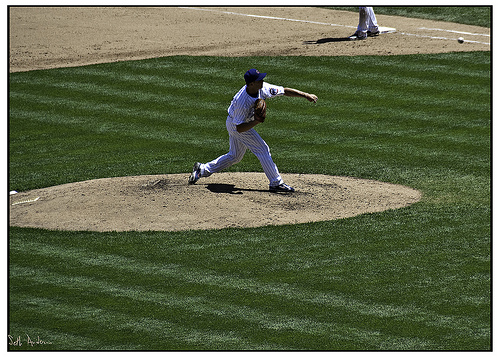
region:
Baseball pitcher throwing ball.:
[172, 38, 312, 227]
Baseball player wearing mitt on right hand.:
[233, 61, 300, 156]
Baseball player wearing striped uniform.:
[178, 43, 325, 220]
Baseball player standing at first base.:
[320, 3, 420, 70]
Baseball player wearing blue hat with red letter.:
[197, 39, 291, 138]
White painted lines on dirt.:
[263, 7, 497, 72]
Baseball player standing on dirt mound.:
[106, 28, 362, 275]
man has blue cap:
[208, 51, 275, 96]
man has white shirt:
[205, 91, 279, 136]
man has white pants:
[197, 124, 345, 192]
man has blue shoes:
[258, 187, 292, 205]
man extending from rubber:
[162, 167, 310, 202]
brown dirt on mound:
[65, 170, 189, 237]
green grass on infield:
[228, 244, 386, 351]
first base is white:
[382, 21, 394, 46]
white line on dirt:
[368, 1, 456, 45]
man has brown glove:
[252, 95, 279, 136]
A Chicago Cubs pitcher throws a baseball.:
[189, 65, 319, 195]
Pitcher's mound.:
[8, 165, 423, 237]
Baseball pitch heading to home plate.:
[454, 35, 465, 44]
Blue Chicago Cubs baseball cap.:
[243, 65, 268, 85]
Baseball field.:
[8, 7, 492, 350]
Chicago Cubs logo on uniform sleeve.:
[268, 85, 278, 95]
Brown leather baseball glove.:
[252, 98, 267, 120]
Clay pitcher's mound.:
[8, 162, 425, 237]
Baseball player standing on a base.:
[348, 5, 381, 42]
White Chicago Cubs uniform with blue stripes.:
[205, 80, 287, 185]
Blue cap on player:
[237, 69, 266, 84]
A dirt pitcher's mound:
[9, 165, 422, 227]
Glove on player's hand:
[251, 93, 267, 119]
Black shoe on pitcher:
[267, 183, 294, 193]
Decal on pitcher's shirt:
[264, 87, 279, 96]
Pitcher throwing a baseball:
[172, 66, 321, 197]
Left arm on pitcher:
[283, 86, 319, 103]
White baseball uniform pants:
[200, 120, 281, 187]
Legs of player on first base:
[342, 9, 384, 37]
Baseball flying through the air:
[450, 35, 467, 47]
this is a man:
[147, 21, 377, 217]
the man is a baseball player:
[167, 19, 370, 226]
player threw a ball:
[174, 5, 488, 246]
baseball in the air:
[441, 14, 480, 62]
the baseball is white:
[441, 28, 484, 56]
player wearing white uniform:
[169, 29, 329, 219]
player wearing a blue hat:
[234, 51, 272, 91]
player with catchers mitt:
[246, 80, 282, 135]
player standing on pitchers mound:
[6, 17, 448, 287]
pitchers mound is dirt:
[14, 94, 437, 264]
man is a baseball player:
[176, 28, 358, 213]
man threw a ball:
[180, 18, 365, 229]